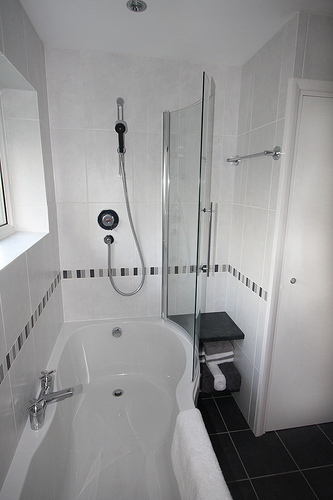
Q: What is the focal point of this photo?
A: A big white tub.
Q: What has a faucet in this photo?
A: A bathtub.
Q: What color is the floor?
A: Black.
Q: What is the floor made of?
A: Tile.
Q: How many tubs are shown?
A: 1.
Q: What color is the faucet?
A: Silver.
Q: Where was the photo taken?
A: A bathroom.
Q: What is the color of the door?
A: White.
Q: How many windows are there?
A: 1.